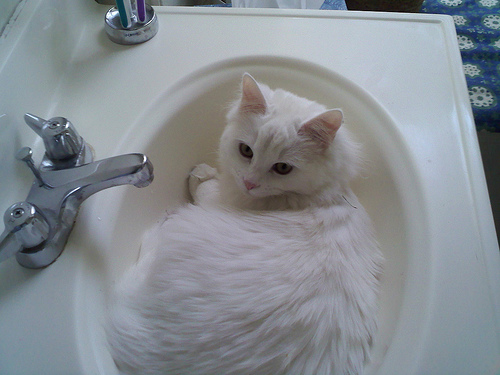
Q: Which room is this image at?
A: It is at the bathroom.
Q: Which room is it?
A: It is a bathroom.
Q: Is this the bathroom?
A: Yes, it is the bathroom.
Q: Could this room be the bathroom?
A: Yes, it is the bathroom.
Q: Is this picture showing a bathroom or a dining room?
A: It is showing a bathroom.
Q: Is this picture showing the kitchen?
A: No, the picture is showing the bathroom.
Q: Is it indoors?
A: Yes, it is indoors.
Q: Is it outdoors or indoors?
A: It is indoors.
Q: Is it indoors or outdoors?
A: It is indoors.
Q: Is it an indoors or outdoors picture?
A: It is indoors.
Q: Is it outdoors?
A: No, it is indoors.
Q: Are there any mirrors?
A: No, there are no mirrors.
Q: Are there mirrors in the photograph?
A: No, there are no mirrors.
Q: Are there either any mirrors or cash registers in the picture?
A: No, there are no mirrors or cash registers.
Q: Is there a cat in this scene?
A: Yes, there is a cat.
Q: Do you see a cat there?
A: Yes, there is a cat.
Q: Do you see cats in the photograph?
A: Yes, there is a cat.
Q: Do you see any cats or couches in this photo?
A: Yes, there is a cat.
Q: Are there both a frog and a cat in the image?
A: No, there is a cat but no frogs.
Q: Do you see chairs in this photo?
A: No, there are no chairs.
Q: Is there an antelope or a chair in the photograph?
A: No, there are no chairs or antelopes.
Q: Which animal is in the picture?
A: The animal is a cat.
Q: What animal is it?
A: The animal is a cat.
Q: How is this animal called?
A: This is a cat.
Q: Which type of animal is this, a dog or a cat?
A: This is a cat.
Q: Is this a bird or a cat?
A: This is a cat.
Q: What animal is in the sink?
A: The cat is in the sink.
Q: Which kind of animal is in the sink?
A: The animal is a cat.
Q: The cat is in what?
A: The cat is in the sink.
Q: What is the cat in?
A: The cat is in the sink.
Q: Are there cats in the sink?
A: Yes, there is a cat in the sink.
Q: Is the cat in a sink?
A: Yes, the cat is in a sink.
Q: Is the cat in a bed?
A: No, the cat is in a sink.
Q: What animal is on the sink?
A: The cat is on the sink.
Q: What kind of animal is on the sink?
A: The animal is a cat.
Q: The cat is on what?
A: The cat is on the sink.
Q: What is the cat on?
A: The cat is on the sink.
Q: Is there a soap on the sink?
A: No, there is a cat on the sink.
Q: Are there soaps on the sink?
A: No, there is a cat on the sink.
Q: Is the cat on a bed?
A: No, the cat is on the sink.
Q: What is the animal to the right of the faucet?
A: The animal is a cat.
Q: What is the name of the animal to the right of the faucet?
A: The animal is a cat.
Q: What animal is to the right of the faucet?
A: The animal is a cat.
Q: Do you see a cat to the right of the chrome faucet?
A: Yes, there is a cat to the right of the faucet.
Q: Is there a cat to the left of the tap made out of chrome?
A: No, the cat is to the right of the faucet.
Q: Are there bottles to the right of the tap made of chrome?
A: No, there is a cat to the right of the faucet.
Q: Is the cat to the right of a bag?
A: No, the cat is to the right of the tap.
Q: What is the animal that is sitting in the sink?
A: The animal is a cat.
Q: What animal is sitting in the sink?
A: The animal is a cat.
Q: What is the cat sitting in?
A: The cat is sitting in the sink.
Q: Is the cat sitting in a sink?
A: Yes, the cat is sitting in a sink.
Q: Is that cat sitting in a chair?
A: No, the cat is sitting in a sink.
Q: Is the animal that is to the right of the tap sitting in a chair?
A: No, the cat is sitting in a sink.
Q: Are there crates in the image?
A: No, there are no crates.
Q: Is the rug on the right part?
A: Yes, the rug is on the right of the image.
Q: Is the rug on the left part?
A: No, the rug is on the right of the image.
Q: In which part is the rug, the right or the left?
A: The rug is on the right of the image.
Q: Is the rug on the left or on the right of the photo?
A: The rug is on the right of the image.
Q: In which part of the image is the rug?
A: The rug is on the right of the image.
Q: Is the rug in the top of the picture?
A: Yes, the rug is in the top of the image.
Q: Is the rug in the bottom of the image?
A: No, the rug is in the top of the image.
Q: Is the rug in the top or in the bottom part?
A: The rug is in the top of the image.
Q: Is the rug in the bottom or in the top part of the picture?
A: The rug is in the top of the image.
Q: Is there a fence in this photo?
A: No, there are no fences.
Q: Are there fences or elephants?
A: No, there are no fences or elephants.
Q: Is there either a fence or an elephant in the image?
A: No, there are no fences or elephants.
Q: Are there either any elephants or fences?
A: No, there are no fences or elephants.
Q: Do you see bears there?
A: No, there are no bears.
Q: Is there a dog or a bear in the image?
A: No, there are no bears or dogs.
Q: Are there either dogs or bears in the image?
A: No, there are no bears or dogs.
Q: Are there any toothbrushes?
A: Yes, there is a toothbrush.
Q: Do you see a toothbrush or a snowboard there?
A: Yes, there is a toothbrush.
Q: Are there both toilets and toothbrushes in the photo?
A: No, there is a toothbrush but no toilets.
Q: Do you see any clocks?
A: No, there are no clocks.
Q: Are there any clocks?
A: No, there are no clocks.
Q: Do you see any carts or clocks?
A: No, there are no clocks or carts.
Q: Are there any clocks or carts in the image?
A: No, there are no clocks or carts.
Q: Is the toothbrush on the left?
A: Yes, the toothbrush is on the left of the image.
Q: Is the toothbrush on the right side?
A: No, the toothbrush is on the left of the image.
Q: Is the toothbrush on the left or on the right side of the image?
A: The toothbrush is on the left of the image.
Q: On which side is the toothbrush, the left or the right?
A: The toothbrush is on the left of the image.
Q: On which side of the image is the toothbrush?
A: The toothbrush is on the left of the image.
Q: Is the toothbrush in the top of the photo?
A: Yes, the toothbrush is in the top of the image.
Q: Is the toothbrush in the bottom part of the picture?
A: No, the toothbrush is in the top of the image.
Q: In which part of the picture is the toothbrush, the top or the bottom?
A: The toothbrush is in the top of the image.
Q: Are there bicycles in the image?
A: No, there are no bicycles.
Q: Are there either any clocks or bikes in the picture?
A: No, there are no bikes or clocks.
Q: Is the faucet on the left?
A: Yes, the faucet is on the left of the image.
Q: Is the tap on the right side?
A: No, the tap is on the left of the image.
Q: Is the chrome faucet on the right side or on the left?
A: The tap is on the left of the image.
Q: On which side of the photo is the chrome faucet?
A: The faucet is on the left of the image.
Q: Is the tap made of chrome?
A: Yes, the tap is made of chrome.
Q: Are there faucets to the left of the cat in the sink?
A: Yes, there is a faucet to the left of the cat.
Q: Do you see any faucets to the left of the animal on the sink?
A: Yes, there is a faucet to the left of the cat.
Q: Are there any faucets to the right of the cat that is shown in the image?
A: No, the faucet is to the left of the cat.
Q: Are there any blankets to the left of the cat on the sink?
A: No, there is a faucet to the left of the cat.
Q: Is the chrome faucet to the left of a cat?
A: Yes, the tap is to the left of a cat.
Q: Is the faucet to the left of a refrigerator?
A: No, the faucet is to the left of a cat.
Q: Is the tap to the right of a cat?
A: No, the tap is to the left of a cat.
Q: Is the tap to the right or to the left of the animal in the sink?
A: The tap is to the left of the cat.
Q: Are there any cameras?
A: Yes, there is a camera.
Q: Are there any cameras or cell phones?
A: Yes, there is a camera.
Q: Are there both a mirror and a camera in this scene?
A: No, there is a camera but no mirrors.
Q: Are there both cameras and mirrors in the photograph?
A: No, there is a camera but no mirrors.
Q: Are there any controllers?
A: No, there are no controllers.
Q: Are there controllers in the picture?
A: No, there are no controllers.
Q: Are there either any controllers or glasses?
A: No, there are no controllers or glasses.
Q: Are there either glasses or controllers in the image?
A: No, there are no controllers or glasses.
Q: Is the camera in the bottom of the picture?
A: Yes, the camera is in the bottom of the image.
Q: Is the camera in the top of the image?
A: No, the camera is in the bottom of the image.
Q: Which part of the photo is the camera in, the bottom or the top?
A: The camera is in the bottom of the image.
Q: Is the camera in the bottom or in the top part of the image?
A: The camera is in the bottom of the image.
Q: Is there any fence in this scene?
A: No, there are no fences.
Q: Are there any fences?
A: No, there are no fences.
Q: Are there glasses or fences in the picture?
A: No, there are no fences or glasses.